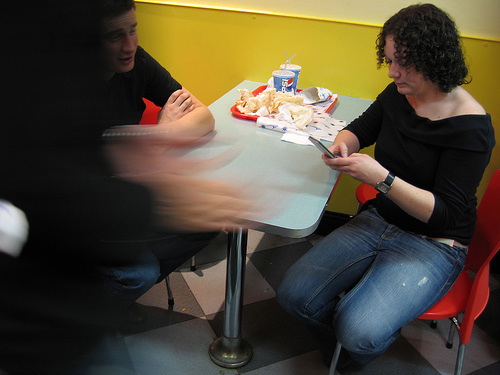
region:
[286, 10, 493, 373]
a woman on a cell phone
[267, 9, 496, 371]
woman wearing blue jeans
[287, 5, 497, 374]
woman sitting in plastic chair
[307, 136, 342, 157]
a silver cell phone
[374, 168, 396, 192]
a dark colored wristwatch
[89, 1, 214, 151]
guy sitting with arms crossed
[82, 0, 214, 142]
a guy sitting in short sleeve shirt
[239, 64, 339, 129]
food on an orange lunch tray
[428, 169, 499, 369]
an orange plastic seat chair with metal legs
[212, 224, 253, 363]
metal support pole for table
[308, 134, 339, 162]
cellphone in a woman's hand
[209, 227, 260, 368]
a metal post on a table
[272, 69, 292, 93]
a blue pepsi cup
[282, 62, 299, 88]
a blue pepsi cup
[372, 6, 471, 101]
a woman's head with curly hair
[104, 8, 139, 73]
face of a man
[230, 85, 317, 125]
food on a tray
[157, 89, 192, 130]
hand of a man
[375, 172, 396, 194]
watch on a woman's wrist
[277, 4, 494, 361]
a woman is sitting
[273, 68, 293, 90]
a cup is blue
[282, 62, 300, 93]
a cup is blue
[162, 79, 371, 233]
a table top is grey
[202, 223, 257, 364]
a metal post for a table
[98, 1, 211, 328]
man is sitting at a table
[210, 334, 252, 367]
metal base of a post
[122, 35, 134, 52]
nose of a man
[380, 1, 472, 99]
Head of person using phone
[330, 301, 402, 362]
Knee of person using phone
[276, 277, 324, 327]
Knee of person using phone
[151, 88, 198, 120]
Hand of person seated across from woman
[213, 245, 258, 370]
Part of table leg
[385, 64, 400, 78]
Nose of woman using phone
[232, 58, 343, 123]
Red tray of leftovers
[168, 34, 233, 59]
Part of golden wall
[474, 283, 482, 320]
Part of woman's red chair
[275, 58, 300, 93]
two beverage pepsi cups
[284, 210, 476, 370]
blue denim jeans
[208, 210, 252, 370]
silver metal pole under table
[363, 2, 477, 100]
a woman with curly hair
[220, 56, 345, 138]
red plastic tray with food on it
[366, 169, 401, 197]
wrist watch on wrist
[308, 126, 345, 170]
cell phone being held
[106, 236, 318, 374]
black and white checkered floor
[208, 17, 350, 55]
yellow painted lower portion of wall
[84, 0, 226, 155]
man with arms crossed on table